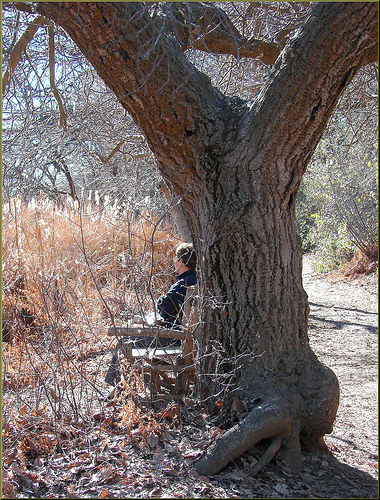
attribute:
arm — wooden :
[106, 323, 191, 342]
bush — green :
[306, 212, 357, 267]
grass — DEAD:
[18, 391, 135, 461]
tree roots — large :
[197, 402, 306, 487]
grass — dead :
[23, 242, 89, 307]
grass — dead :
[3, 190, 165, 332]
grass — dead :
[20, 215, 63, 249]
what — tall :
[86, 187, 123, 274]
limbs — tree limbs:
[184, 23, 378, 169]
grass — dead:
[323, 249, 374, 289]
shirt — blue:
[141, 266, 221, 337]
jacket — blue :
[119, 270, 204, 315]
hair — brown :
[172, 240, 199, 271]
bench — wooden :
[111, 287, 204, 390]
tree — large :
[2, 1, 378, 477]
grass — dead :
[2, 238, 376, 498]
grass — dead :
[1, 184, 183, 498]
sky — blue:
[27, 62, 50, 97]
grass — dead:
[345, 371, 371, 460]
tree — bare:
[18, 17, 375, 391]